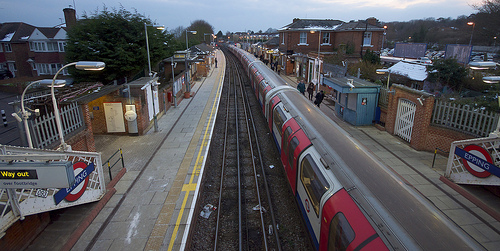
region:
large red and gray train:
[216, 37, 471, 249]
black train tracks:
[187, 40, 306, 248]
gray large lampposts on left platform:
[17, 55, 106, 152]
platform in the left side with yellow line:
[17, 45, 227, 249]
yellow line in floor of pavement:
[157, 43, 224, 248]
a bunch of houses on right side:
[238, 13, 498, 156]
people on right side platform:
[296, 77, 326, 106]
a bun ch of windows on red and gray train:
[224, 43, 358, 248]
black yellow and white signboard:
[0, 162, 72, 227]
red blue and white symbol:
[52, 161, 101, 206]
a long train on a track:
[202, 34, 447, 249]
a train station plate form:
[130, 37, 231, 243]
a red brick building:
[285, 13, 367, 82]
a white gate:
[380, 89, 435, 149]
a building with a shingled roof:
[302, 19, 370, 49]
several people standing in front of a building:
[239, 38, 302, 78]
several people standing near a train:
[247, 32, 289, 83]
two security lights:
[20, 44, 110, 173]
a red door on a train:
[245, 112, 330, 208]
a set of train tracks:
[213, 79, 257, 247]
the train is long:
[251, 64, 396, 249]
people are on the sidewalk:
[248, 43, 333, 101]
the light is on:
[75, 60, 106, 80]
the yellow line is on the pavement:
[181, 140, 211, 186]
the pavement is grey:
[148, 129, 178, 169]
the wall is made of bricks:
[99, 97, 149, 132]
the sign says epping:
[454, 143, 496, 176]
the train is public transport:
[225, 27, 410, 249]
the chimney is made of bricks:
[60, 5, 87, 29]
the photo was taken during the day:
[14, 10, 496, 249]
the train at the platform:
[252, 78, 412, 248]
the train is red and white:
[275, 108, 425, 249]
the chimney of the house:
[55, 5, 80, 30]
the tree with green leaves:
[87, 21, 146, 74]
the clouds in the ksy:
[180, 4, 268, 19]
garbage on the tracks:
[242, 197, 264, 216]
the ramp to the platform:
[0, 142, 110, 209]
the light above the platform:
[67, 51, 114, 81]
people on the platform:
[298, 76, 328, 101]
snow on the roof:
[299, 18, 344, 35]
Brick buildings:
[0, 22, 94, 94]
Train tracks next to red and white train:
[204, 25, 287, 245]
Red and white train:
[227, 40, 469, 247]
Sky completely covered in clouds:
[0, 1, 475, 21]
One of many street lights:
[461, 19, 487, 44]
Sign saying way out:
[0, 167, 45, 184]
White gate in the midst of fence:
[391, 94, 417, 146]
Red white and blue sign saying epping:
[460, 140, 492, 180]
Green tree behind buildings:
[75, 10, 172, 78]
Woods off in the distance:
[382, 7, 493, 43]